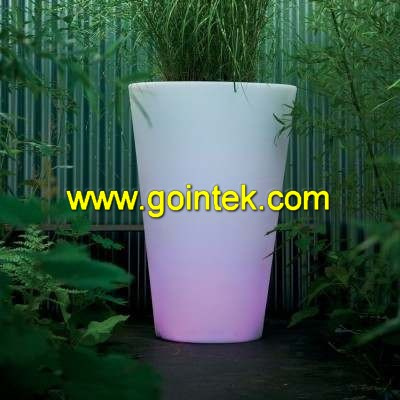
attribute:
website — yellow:
[66, 183, 330, 219]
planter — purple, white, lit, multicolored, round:
[126, 79, 299, 347]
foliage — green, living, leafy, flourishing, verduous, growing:
[83, 2, 289, 81]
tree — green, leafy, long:
[274, 0, 398, 230]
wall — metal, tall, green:
[1, 2, 399, 314]